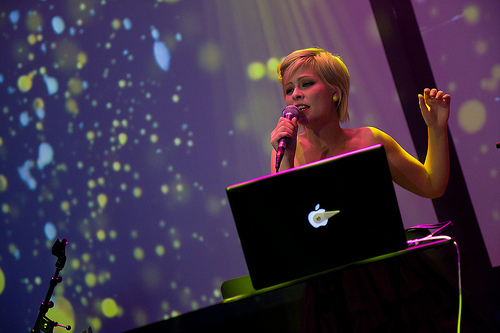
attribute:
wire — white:
[408, 235, 464, 331]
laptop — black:
[227, 144, 408, 290]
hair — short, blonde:
[283, 45, 357, 128]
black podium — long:
[116, 236, 463, 331]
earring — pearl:
[331, 88, 343, 104]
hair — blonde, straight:
[315, 50, 347, 94]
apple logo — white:
[306, 202, 331, 229]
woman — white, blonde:
[271, 47, 449, 197]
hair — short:
[280, 46, 349, 121]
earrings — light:
[332, 94, 339, 102]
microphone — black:
[269, 102, 301, 172]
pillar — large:
[373, 16, 477, 131]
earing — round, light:
[329, 92, 343, 102]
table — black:
[93, 231, 466, 331]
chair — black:
[214, 269, 256, 299]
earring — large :
[324, 81, 347, 113]